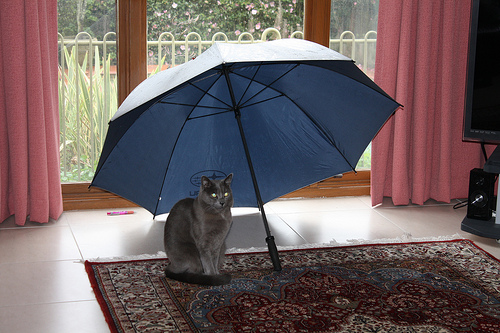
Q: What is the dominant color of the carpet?
A: Red.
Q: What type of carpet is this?
A: Oriental.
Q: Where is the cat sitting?
A: Carpet.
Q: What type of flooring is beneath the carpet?
A: Tile.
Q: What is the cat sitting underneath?
A: Umbrella.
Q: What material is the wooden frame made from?
A: Wood.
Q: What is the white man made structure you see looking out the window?
A: Fence.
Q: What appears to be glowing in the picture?
A: Cat's eyes.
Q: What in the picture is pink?
A: Drapes.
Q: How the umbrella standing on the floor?
A: Propped open.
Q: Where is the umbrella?
A: Floor in the living room.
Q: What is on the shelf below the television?
A: Small speaker.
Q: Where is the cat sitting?
A: A rug on the floor.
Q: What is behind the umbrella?
A: A glass door.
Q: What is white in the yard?
A: Fence.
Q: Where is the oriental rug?
A: On the floor.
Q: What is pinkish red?
A: The curtains.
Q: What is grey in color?
A: The cat.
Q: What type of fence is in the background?
A: An ornamental fence.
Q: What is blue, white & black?
A: The umbrella.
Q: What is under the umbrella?
A: The black cat.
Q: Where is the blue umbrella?
A: On the floor.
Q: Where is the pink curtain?
A: On the left door.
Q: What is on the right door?
A: A pink curtain.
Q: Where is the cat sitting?
A: Under the umbrella.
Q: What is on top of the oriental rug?
A: The cat.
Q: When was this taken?
A: Day time.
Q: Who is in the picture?
A: A cat.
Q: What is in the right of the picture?
A: A speaker.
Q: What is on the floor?
A: A rug.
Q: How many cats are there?
A: One.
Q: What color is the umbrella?
A: Blue.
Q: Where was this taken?
A: In a house.